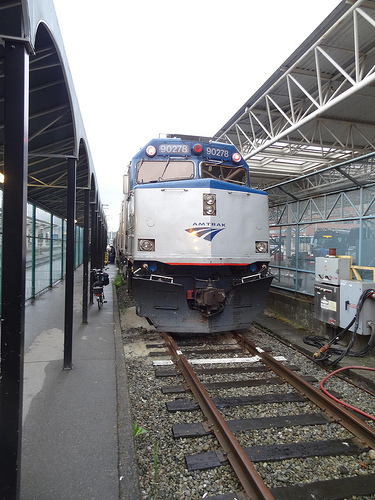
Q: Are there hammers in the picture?
A: No, there are no hammers.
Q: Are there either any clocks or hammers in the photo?
A: No, there are no hammers or clocks.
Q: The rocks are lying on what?
A: The rocks are lying on the ground.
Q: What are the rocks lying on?
A: The rocks are lying on the ground.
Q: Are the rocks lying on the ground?
A: Yes, the rocks are lying on the ground.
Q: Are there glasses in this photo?
A: No, there are no glasses.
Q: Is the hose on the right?
A: Yes, the hose is on the right of the image.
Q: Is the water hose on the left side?
A: No, the water hose is on the right of the image.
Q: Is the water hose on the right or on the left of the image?
A: The water hose is on the right of the image.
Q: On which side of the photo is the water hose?
A: The water hose is on the right of the image.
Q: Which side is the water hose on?
A: The water hose is on the right of the image.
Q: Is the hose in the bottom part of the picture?
A: Yes, the hose is in the bottom of the image.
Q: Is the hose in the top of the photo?
A: No, the hose is in the bottom of the image.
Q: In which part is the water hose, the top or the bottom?
A: The water hose is in the bottom of the image.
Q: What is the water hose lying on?
A: The water hose is lying on the ground.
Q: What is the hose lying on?
A: The water hose is lying on the ground.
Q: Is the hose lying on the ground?
A: Yes, the hose is lying on the ground.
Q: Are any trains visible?
A: Yes, there is a train.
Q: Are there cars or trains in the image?
A: Yes, there is a train.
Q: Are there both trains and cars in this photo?
A: No, there is a train but no cars.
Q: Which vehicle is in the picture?
A: The vehicle is a train.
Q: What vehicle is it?
A: The vehicle is a train.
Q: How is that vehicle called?
A: This is a train.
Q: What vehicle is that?
A: This is a train.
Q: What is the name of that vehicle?
A: This is a train.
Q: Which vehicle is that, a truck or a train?
A: This is a train.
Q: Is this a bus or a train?
A: This is a train.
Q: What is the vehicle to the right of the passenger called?
A: The vehicle is a train.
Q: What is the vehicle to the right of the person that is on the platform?
A: The vehicle is a train.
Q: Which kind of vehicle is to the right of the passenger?
A: The vehicle is a train.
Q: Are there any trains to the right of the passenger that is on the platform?
A: Yes, there is a train to the right of the passenger.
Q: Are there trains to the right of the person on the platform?
A: Yes, there is a train to the right of the passenger.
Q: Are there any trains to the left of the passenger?
A: No, the train is to the right of the passenger.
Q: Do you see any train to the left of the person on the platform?
A: No, the train is to the right of the passenger.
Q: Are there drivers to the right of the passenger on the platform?
A: No, there is a train to the right of the passenger.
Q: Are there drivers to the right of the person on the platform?
A: No, there is a train to the right of the passenger.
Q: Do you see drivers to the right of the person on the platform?
A: No, there is a train to the right of the passenger.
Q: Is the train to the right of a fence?
A: No, the train is to the right of a passenger.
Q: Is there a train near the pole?
A: Yes, there is a train near the pole.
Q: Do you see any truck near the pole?
A: No, there is a train near the pole.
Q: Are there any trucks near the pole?
A: No, there is a train near the pole.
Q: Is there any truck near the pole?
A: No, there is a train near the pole.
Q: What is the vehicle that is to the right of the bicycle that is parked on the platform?
A: The vehicle is a train.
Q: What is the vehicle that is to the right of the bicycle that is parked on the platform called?
A: The vehicle is a train.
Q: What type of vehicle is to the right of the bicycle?
A: The vehicle is a train.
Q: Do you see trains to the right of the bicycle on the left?
A: Yes, there is a train to the right of the bicycle.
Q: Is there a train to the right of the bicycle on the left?
A: Yes, there is a train to the right of the bicycle.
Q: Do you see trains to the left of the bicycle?
A: No, the train is to the right of the bicycle.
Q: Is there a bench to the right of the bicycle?
A: No, there is a train to the right of the bicycle.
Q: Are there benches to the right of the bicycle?
A: No, there is a train to the right of the bicycle.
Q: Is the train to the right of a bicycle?
A: Yes, the train is to the right of a bicycle.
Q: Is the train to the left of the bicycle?
A: No, the train is to the right of the bicycle.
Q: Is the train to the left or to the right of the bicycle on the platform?
A: The train is to the right of the bicycle.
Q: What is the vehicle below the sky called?
A: The vehicle is a train.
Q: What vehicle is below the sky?
A: The vehicle is a train.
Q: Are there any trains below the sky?
A: Yes, there is a train below the sky.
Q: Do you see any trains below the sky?
A: Yes, there is a train below the sky.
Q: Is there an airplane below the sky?
A: No, there is a train below the sky.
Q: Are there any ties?
A: Yes, there is a tie.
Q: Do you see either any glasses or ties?
A: Yes, there is a tie.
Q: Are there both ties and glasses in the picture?
A: No, there is a tie but no glasses.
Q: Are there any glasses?
A: No, there are no glasses.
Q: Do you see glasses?
A: No, there are no glasses.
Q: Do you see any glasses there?
A: No, there are no glasses.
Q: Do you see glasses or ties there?
A: Yes, there is a tie.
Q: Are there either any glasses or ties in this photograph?
A: Yes, there is a tie.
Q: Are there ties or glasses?
A: Yes, there is a tie.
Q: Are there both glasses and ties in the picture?
A: No, there is a tie but no glasses.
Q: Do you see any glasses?
A: No, there are no glasses.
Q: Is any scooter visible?
A: No, there are no scooters.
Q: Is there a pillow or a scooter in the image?
A: No, there are no scooters or pillows.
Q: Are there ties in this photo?
A: Yes, there is a tie.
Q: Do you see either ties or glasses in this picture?
A: Yes, there is a tie.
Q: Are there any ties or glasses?
A: Yes, there is a tie.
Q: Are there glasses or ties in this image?
A: Yes, there is a tie.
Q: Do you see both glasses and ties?
A: No, there is a tie but no glasses.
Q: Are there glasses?
A: No, there are no glasses.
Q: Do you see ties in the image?
A: Yes, there is a tie.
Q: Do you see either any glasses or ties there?
A: Yes, there is a tie.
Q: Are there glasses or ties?
A: Yes, there is a tie.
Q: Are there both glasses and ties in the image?
A: No, there is a tie but no glasses.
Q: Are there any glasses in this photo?
A: No, there are no glasses.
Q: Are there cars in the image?
A: No, there are no cars.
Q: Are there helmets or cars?
A: No, there are no cars or helmets.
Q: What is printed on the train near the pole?
A: The number is printed on the train.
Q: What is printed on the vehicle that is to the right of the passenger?
A: The number is printed on the train.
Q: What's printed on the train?
A: The number is printed on the train.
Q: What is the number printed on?
A: The number is printed on the train.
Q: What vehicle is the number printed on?
A: The number is printed on the train.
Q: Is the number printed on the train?
A: Yes, the number is printed on the train.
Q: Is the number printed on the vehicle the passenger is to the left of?
A: Yes, the number is printed on the train.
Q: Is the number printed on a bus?
A: No, the number is printed on the train.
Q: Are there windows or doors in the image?
A: Yes, there is a window.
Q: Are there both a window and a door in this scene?
A: No, there is a window but no doors.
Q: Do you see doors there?
A: No, there are no doors.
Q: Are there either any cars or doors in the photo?
A: No, there are no doors or cars.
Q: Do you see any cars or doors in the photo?
A: No, there are no doors or cars.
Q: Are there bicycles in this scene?
A: Yes, there is a bicycle.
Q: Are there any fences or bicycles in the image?
A: Yes, there is a bicycle.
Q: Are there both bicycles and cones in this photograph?
A: No, there is a bicycle but no cones.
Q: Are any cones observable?
A: No, there are no cones.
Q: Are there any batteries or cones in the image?
A: No, there are no cones or batteries.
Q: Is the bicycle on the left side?
A: Yes, the bicycle is on the left of the image.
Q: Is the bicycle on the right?
A: No, the bicycle is on the left of the image.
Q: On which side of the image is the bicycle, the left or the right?
A: The bicycle is on the left of the image.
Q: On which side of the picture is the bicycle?
A: The bicycle is on the left of the image.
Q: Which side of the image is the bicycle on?
A: The bicycle is on the left of the image.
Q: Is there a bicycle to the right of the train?
A: No, the bicycle is to the left of the train.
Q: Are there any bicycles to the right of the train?
A: No, the bicycle is to the left of the train.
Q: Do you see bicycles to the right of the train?
A: No, the bicycle is to the left of the train.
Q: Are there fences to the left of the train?
A: No, there is a bicycle to the left of the train.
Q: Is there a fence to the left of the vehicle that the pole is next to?
A: No, there is a bicycle to the left of the train.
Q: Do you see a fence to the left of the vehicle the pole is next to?
A: No, there is a bicycle to the left of the train.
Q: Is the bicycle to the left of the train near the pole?
A: Yes, the bicycle is to the left of the train.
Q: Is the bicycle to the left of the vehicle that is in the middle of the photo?
A: Yes, the bicycle is to the left of the train.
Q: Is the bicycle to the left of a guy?
A: No, the bicycle is to the left of the train.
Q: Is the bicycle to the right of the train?
A: No, the bicycle is to the left of the train.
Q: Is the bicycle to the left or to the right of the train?
A: The bicycle is to the left of the train.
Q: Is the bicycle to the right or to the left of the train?
A: The bicycle is to the left of the train.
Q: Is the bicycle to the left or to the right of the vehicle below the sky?
A: The bicycle is to the left of the train.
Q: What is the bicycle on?
A: The bicycle is on the platform.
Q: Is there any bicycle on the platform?
A: Yes, there is a bicycle on the platform.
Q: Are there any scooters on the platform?
A: No, there is a bicycle on the platform.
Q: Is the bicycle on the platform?
A: Yes, the bicycle is on the platform.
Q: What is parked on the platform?
A: The bicycle is parked on the platform.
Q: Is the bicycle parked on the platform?
A: Yes, the bicycle is parked on the platform.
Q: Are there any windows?
A: Yes, there is a window.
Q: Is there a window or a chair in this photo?
A: Yes, there is a window.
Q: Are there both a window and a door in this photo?
A: No, there is a window but no doors.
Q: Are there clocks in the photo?
A: No, there are no clocks.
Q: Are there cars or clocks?
A: No, there are no clocks or cars.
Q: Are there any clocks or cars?
A: No, there are no clocks or cars.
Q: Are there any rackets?
A: No, there are no rackets.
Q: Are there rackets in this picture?
A: No, there are no rackets.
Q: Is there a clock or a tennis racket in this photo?
A: No, there are no rackets or clocks.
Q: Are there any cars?
A: No, there are no cars.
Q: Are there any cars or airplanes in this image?
A: No, there are no cars or airplanes.